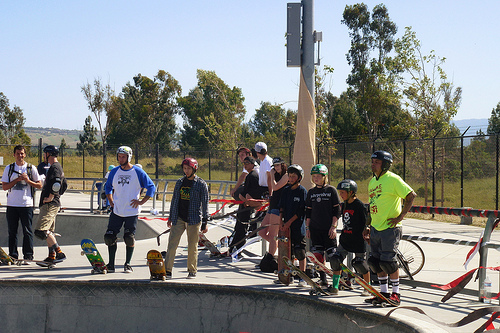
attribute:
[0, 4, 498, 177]
trees — green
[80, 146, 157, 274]
skater — ready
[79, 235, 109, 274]
skateboard — here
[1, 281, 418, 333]
ramp — gray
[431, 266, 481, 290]
streamer — waving, red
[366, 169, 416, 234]
shirt — green, yellow, bright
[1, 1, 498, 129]
sky — clear, blue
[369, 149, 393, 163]
helmet — black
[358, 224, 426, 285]
bike — parked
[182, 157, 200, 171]
helmet — red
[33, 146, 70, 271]
person — turned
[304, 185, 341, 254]
clothes — dark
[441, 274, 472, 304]
streamer — black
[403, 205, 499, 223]
railing — wrapped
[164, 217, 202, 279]
pants — tan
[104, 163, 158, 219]
shirt — blue, white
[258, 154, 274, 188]
shirt — white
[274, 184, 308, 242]
shirt — black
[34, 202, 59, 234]
shorts — tan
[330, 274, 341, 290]
socks — green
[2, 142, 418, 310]
people — watching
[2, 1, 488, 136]
day — bright, sunny